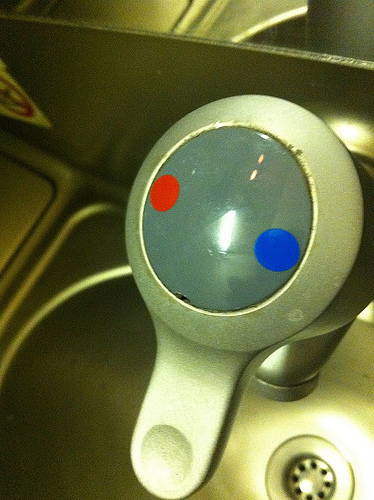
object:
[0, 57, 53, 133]
sign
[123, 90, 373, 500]
faucet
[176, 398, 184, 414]
edge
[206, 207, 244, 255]
light reflecting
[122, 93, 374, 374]
handle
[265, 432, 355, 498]
drain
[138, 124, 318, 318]
circular insert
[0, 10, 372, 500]
sink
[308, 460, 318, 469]
hole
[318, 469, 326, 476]
hole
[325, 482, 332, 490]
hole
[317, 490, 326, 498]
hole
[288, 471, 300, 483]
hole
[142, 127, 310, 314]
top center